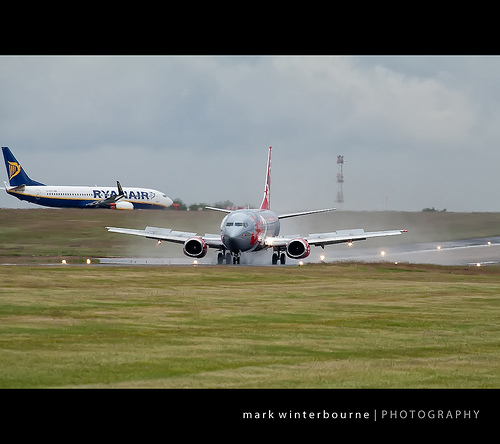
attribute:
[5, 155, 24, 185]
logo — company logo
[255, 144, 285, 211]
white plane's tail — red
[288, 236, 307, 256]
red propeller — silver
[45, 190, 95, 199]
row of windows — long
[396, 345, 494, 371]
patches of grass — dried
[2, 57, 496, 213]
sky — cloudy, overcast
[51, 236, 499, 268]
runway — lit, wet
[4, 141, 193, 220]
plane — white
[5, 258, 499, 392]
grass field — flat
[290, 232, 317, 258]
engine — large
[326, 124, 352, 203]
tower — distant, metal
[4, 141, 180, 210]
white plane — blue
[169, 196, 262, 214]
group of plants — distant